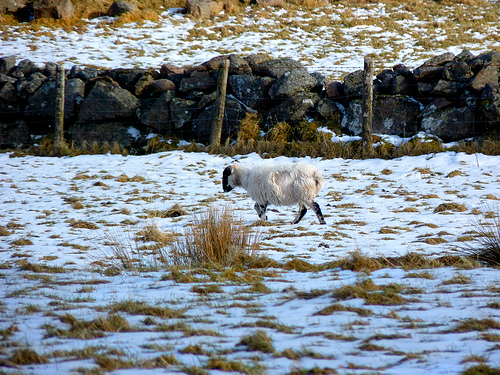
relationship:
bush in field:
[240, 110, 338, 161] [24, 128, 444, 320]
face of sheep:
[219, 166, 232, 196] [221, 157, 331, 228]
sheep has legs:
[221, 157, 331, 228] [253, 198, 331, 228]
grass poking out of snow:
[103, 229, 144, 282] [162, 161, 192, 181]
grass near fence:
[103, 229, 144, 282] [49, 54, 93, 162]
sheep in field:
[221, 157, 331, 228] [24, 128, 444, 320]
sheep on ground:
[221, 157, 331, 228] [260, 221, 328, 252]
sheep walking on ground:
[221, 157, 331, 228] [260, 221, 328, 252]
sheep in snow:
[221, 157, 331, 228] [162, 161, 192, 181]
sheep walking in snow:
[221, 157, 331, 228] [162, 161, 192, 181]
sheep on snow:
[221, 157, 331, 228] [162, 161, 192, 181]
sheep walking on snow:
[221, 157, 331, 228] [162, 161, 192, 181]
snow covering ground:
[162, 161, 192, 181] [260, 221, 328, 252]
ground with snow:
[260, 221, 328, 252] [162, 161, 192, 181]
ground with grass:
[260, 221, 328, 252] [103, 229, 144, 282]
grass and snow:
[103, 229, 144, 282] [162, 161, 192, 181]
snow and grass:
[162, 161, 192, 181] [103, 229, 144, 282]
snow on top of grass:
[162, 161, 192, 181] [103, 229, 144, 282]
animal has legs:
[221, 157, 331, 228] [253, 198, 331, 228]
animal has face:
[221, 157, 331, 228] [219, 166, 232, 196]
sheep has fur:
[221, 157, 331, 228] [296, 177, 315, 205]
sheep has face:
[221, 157, 331, 228] [219, 166, 232, 196]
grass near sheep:
[103, 229, 144, 282] [221, 157, 331, 228]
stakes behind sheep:
[211, 50, 388, 153] [221, 157, 331, 228]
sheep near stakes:
[221, 157, 331, 228] [211, 50, 388, 153]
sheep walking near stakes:
[221, 157, 331, 228] [211, 50, 388, 153]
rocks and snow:
[0, 55, 50, 120] [162, 161, 192, 181]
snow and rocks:
[162, 161, 192, 181] [0, 55, 50, 120]